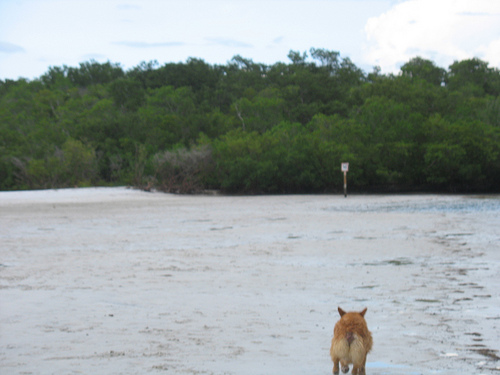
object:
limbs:
[127, 152, 217, 190]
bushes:
[110, 98, 290, 189]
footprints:
[427, 221, 499, 370]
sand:
[0, 213, 494, 371]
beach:
[9, 208, 81, 362]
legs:
[330, 357, 369, 374]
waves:
[409, 199, 497, 366]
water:
[457, 212, 491, 238]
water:
[452, 199, 492, 220]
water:
[446, 277, 493, 370]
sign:
[332, 147, 374, 214]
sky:
[8, 6, 495, 91]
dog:
[272, 268, 416, 360]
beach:
[103, 199, 343, 371]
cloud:
[356, 1, 497, 68]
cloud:
[3, 0, 265, 69]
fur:
[339, 323, 364, 359]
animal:
[328, 306, 373, 374]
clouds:
[354, 7, 498, 58]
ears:
[325, 302, 350, 320]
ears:
[359, 300, 376, 312]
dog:
[312, 280, 398, 372]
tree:
[379, 59, 455, 191]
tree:
[266, 120, 333, 191]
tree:
[132, 79, 235, 152]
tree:
[34, 70, 126, 172]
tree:
[2, 77, 64, 182]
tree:
[95, 77, 176, 187]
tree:
[170, 65, 260, 187]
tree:
[260, 57, 340, 124]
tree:
[324, 75, 386, 193]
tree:
[401, 56, 497, 191]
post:
[338, 180, 354, 190]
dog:
[324, 303, 376, 373]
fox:
[328, 306, 372, 373]